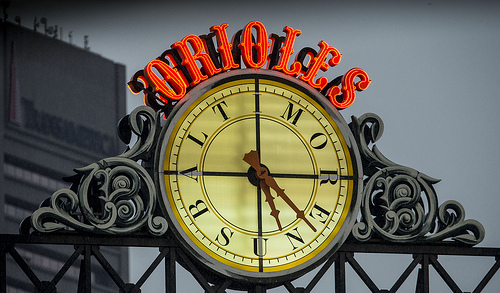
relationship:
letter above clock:
[145, 57, 185, 102] [140, 67, 365, 286]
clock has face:
[140, 67, 365, 286] [165, 78, 353, 270]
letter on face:
[281, 100, 304, 125] [165, 78, 353, 270]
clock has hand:
[140, 67, 365, 286] [241, 148, 316, 231]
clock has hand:
[140, 67, 365, 286] [260, 181, 282, 233]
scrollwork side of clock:
[347, 111, 487, 246] [140, 67, 365, 286]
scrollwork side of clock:
[16, 108, 169, 239] [140, 67, 365, 286]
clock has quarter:
[140, 67, 365, 286] [163, 78, 262, 179]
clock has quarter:
[140, 67, 365, 286] [256, 77, 353, 181]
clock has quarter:
[140, 67, 365, 286] [165, 173, 261, 269]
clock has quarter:
[140, 67, 365, 286] [259, 177, 358, 268]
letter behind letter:
[126, 69, 168, 113] [145, 57, 185, 102]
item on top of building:
[82, 31, 90, 50] [2, 19, 132, 292]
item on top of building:
[14, 13, 22, 27] [2, 19, 132, 292]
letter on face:
[215, 223, 236, 250] [165, 78, 353, 270]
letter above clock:
[328, 66, 371, 110] [140, 67, 365, 286]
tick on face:
[264, 86, 269, 94] [165, 78, 353, 270]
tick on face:
[317, 116, 324, 124] [165, 78, 353, 270]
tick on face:
[224, 249, 228, 256] [165, 78, 353, 270]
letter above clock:
[239, 20, 268, 70] [140, 67, 365, 286]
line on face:
[253, 77, 268, 272] [165, 78, 353, 270]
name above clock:
[144, 20, 371, 111] [140, 67, 365, 286]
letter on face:
[309, 200, 332, 224] [165, 78, 353, 270]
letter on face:
[284, 224, 307, 249] [165, 78, 353, 270]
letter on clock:
[185, 199, 209, 220] [140, 67, 365, 286]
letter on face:
[180, 161, 201, 181] [165, 78, 353, 270]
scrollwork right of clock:
[347, 111, 487, 246] [140, 67, 365, 286]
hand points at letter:
[260, 181, 282, 233] [284, 224, 307, 249]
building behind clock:
[2, 19, 132, 292] [140, 67, 365, 286]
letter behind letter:
[199, 31, 222, 70] [209, 23, 237, 71]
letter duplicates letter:
[199, 31, 222, 70] [209, 23, 237, 71]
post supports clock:
[164, 247, 174, 292] [140, 67, 365, 286]